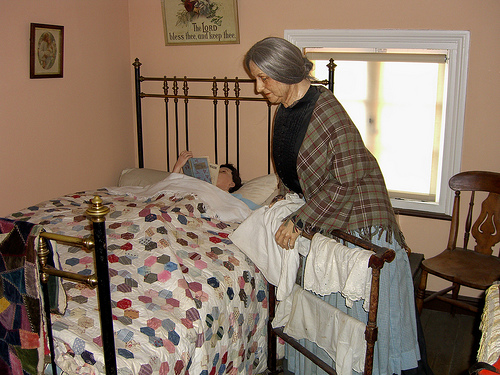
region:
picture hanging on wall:
[30, 18, 75, 89]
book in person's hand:
[184, 153, 215, 185]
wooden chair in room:
[427, 168, 496, 332]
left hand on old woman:
[272, 213, 302, 254]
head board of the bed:
[131, 66, 345, 176]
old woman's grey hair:
[259, 38, 312, 79]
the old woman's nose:
[256, 76, 262, 96]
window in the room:
[315, 36, 455, 199]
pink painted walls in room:
[54, 112, 133, 169]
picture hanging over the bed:
[151, 1, 253, 46]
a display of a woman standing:
[7, 2, 414, 350]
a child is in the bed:
[105, 125, 253, 232]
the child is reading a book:
[139, 124, 241, 231]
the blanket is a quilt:
[0, 142, 245, 369]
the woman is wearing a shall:
[218, 19, 392, 248]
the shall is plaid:
[258, 60, 411, 247]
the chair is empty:
[417, 157, 498, 294]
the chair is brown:
[412, 152, 497, 302]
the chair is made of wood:
[410, 170, 498, 317]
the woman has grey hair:
[218, 12, 346, 129]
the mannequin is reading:
[171, 142, 258, 236]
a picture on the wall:
[13, 8, 100, 118]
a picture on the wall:
[14, 5, 89, 103]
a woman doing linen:
[213, 36, 461, 361]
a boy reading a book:
[171, 146, 246, 201]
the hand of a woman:
[272, 215, 303, 250]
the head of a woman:
[233, 34, 322, 123]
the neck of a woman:
[283, 75, 315, 118]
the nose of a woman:
[250, 78, 264, 96]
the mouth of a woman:
[261, 90, 271, 100]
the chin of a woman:
[268, 96, 278, 105]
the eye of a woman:
[261, 70, 267, 83]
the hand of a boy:
[170, 148, 195, 178]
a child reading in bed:
[156, 147, 243, 208]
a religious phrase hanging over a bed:
[155, 0, 245, 49]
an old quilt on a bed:
[8, 181, 280, 373]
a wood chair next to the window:
[389, 34, 499, 312]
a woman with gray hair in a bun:
[232, 33, 414, 373]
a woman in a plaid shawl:
[231, 33, 408, 256]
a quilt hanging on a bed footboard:
[0, 208, 80, 374]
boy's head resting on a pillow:
[210, 158, 271, 207]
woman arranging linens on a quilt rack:
[227, 31, 394, 373]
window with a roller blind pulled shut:
[282, 29, 458, 214]